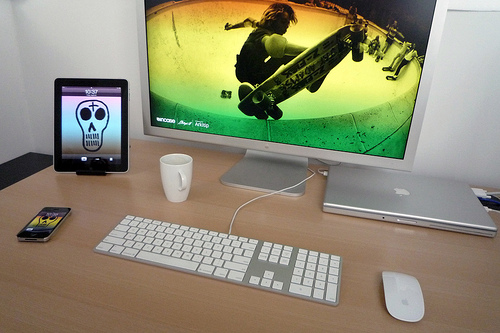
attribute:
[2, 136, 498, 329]
desk — brown, wooden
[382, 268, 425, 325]
mouse — white, wireless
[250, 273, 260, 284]
key — white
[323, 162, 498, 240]
laptop — closed, silver colored, silver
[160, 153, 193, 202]
cup — white, empty, ceramic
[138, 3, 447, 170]
monitor — on, silver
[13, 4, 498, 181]
wall — white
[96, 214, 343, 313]
keyboard — grey, white, apple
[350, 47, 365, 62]
wheel — rubber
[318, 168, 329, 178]
cord — white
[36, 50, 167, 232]
ipad — apple